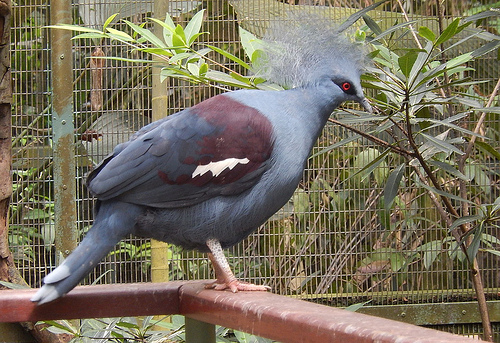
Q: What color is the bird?
A: Gray, white, and maroon.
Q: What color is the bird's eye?
A: Red and black.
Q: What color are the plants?
A: Green.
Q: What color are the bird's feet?
A: Orange.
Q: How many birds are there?
A: One.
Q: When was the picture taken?
A: Daytime.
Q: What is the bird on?
A: Bars.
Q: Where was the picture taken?
A: At a zoo.